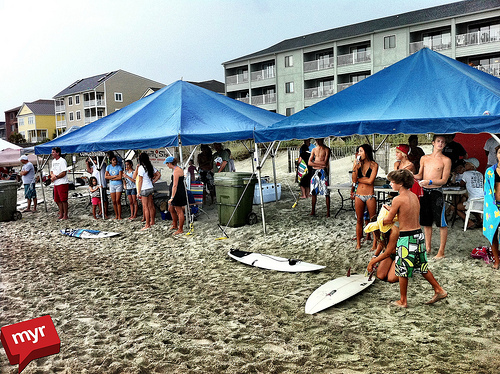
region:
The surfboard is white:
[318, 271, 334, 350]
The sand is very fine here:
[142, 268, 157, 360]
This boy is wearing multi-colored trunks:
[400, 218, 417, 310]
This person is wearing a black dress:
[172, 181, 180, 255]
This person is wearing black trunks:
[426, 178, 442, 271]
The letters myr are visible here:
[3, 301, 33, 359]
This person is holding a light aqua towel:
[481, 170, 492, 230]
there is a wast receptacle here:
[219, 173, 239, 263]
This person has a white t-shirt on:
[135, 172, 143, 197]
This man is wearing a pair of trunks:
[24, 183, 37, 212]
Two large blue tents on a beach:
[44, 33, 499, 239]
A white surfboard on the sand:
[300, 273, 377, 316]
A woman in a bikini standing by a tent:
[347, 143, 382, 252]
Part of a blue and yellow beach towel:
[479, 163, 499, 245]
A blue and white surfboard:
[58, 223, 123, 242]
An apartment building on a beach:
[223, 1, 498, 139]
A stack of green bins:
[212, 169, 256, 227]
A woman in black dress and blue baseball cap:
[158, 154, 190, 234]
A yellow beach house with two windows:
[16, 97, 56, 142]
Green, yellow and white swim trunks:
[393, 230, 427, 281]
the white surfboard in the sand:
[57, 227, 113, 242]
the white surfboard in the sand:
[227, 246, 324, 283]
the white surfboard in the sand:
[302, 271, 374, 313]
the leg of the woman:
[111, 185, 117, 219]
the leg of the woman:
[114, 186, 122, 216]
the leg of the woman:
[125, 188, 132, 215]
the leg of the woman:
[130, 188, 138, 216]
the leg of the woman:
[140, 188, 146, 224]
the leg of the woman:
[145, 188, 155, 224]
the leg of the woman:
[167, 201, 177, 229]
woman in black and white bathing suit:
[350, 141, 380, 250]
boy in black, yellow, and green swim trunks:
[384, 170, 446, 307]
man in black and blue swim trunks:
[415, 132, 450, 255]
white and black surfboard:
[304, 265, 378, 310]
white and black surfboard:
[227, 245, 327, 274]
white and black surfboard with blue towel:
[59, 225, 121, 237]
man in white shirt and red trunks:
[49, 147, 70, 217]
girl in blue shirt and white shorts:
[106, 155, 123, 220]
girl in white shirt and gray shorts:
[135, 153, 157, 229]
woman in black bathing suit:
[164, 155, 187, 232]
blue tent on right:
[247, 38, 498, 235]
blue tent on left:
[23, 79, 300, 224]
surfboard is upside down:
[291, 255, 381, 322]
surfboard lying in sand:
[226, 237, 323, 284]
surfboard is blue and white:
[58, 216, 123, 250]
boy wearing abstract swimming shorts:
[385, 221, 443, 286]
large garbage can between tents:
[206, 161, 260, 227]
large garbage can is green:
[206, 166, 264, 231]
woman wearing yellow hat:
[353, 194, 404, 240]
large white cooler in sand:
[247, 172, 286, 206]